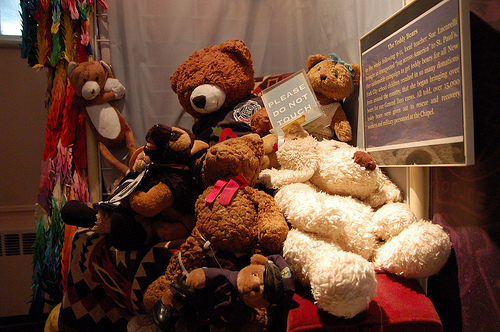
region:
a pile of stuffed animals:
[57, 26, 464, 329]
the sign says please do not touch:
[236, 60, 345, 180]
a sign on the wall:
[344, 1, 498, 238]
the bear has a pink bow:
[174, 137, 306, 276]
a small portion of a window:
[1, 0, 46, 63]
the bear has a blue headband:
[279, 41, 374, 141]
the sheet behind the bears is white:
[86, 3, 453, 198]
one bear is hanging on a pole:
[51, 7, 166, 239]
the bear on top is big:
[153, 32, 303, 164]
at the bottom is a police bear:
[143, 240, 303, 328]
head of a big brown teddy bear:
[167, 38, 255, 118]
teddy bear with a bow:
[303, 54, 360, 142]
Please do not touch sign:
[262, 71, 323, 131]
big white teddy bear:
[276, 139, 453, 318]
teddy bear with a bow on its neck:
[142, 132, 288, 314]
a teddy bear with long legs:
[63, 61, 133, 172]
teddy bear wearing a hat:
[153, 251, 296, 325]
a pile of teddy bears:
[64, 39, 447, 329]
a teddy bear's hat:
[262, 253, 295, 308]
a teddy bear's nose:
[188, 93, 210, 108]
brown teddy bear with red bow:
[200, 136, 271, 266]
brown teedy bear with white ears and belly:
[63, 48, 139, 200]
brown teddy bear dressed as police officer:
[190, 261, 304, 327]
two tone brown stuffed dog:
[131, 109, 206, 214]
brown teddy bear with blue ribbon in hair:
[301, 46, 368, 112]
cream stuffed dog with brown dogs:
[283, 122, 429, 329]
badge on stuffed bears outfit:
[227, 97, 289, 154]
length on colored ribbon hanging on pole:
[19, 6, 84, 241]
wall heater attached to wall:
[1, 197, 90, 314]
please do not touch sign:
[251, 66, 344, 151]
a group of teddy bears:
[70, 44, 422, 312]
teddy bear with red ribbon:
[196, 135, 287, 255]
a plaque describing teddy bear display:
[347, 11, 483, 151]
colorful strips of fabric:
[9, 5, 89, 280]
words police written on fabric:
[423, 167, 498, 227]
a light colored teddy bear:
[264, 125, 459, 316]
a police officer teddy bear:
[151, 253, 298, 323]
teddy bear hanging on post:
[11, 7, 140, 162]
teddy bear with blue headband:
[297, 34, 360, 146]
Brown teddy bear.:
[171, 42, 246, 111]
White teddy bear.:
[291, 149, 438, 289]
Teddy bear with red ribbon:
[214, 177, 243, 209]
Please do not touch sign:
[263, 83, 325, 133]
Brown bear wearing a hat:
[245, 251, 295, 308]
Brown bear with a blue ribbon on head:
[327, 52, 354, 72]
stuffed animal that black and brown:
[145, 124, 199, 169]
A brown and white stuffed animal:
[69, 64, 122, 114]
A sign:
[359, 35, 477, 153]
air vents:
[7, 230, 27, 259]